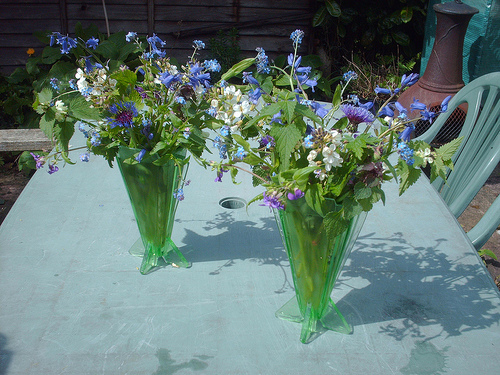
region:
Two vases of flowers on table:
[32, 18, 437, 344]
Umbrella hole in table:
[210, 194, 250, 214]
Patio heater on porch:
[392, 1, 478, 150]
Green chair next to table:
[411, 69, 498, 247]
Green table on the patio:
[2, 84, 493, 373]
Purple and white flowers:
[30, 15, 457, 205]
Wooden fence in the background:
[2, 0, 325, 102]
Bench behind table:
[0, 127, 62, 155]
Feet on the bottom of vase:
[272, 286, 357, 343]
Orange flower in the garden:
[15, 43, 42, 69]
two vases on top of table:
[11, 30, 462, 343]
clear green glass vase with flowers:
[98, 139, 194, 272]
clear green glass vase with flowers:
[271, 188, 369, 342]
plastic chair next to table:
[399, 70, 498, 248]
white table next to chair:
[0, 97, 496, 372]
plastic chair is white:
[407, 67, 497, 256]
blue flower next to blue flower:
[202, 57, 223, 73]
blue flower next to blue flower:
[384, 71, 396, 93]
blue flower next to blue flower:
[402, 125, 413, 143]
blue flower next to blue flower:
[104, 99, 143, 130]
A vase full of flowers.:
[208, 29, 460, 349]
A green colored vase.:
[271, 189, 368, 345]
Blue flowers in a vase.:
[18, 17, 255, 277]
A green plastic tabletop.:
[0, 95, 499, 372]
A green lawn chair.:
[406, 68, 499, 248]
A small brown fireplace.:
[392, 1, 479, 141]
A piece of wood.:
[0, 124, 67, 152]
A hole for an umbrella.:
[220, 195, 247, 212]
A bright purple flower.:
[258, 191, 288, 211]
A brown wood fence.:
[1, 0, 313, 85]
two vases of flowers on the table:
[59, 34, 393, 340]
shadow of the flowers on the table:
[362, 230, 491, 345]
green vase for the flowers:
[284, 206, 348, 343]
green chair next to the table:
[421, 74, 486, 222]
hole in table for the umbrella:
[216, 192, 248, 217]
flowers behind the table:
[8, 37, 33, 117]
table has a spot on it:
[148, 336, 208, 373]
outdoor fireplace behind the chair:
[401, 8, 468, 133]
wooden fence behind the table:
[148, 8, 264, 54]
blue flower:
[396, 72, 416, 91]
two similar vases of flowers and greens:
[2, 5, 493, 370]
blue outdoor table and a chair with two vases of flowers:
[12, 3, 495, 368]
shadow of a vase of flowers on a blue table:
[328, 232, 493, 337]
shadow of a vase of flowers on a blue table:
[163, 208, 295, 295]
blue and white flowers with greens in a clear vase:
[22, 29, 244, 272]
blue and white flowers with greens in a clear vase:
[195, 30, 457, 345]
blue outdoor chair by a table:
[407, 69, 497, 248]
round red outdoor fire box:
[397, 1, 477, 158]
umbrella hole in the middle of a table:
[217, 195, 248, 211]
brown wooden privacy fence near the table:
[5, 2, 335, 124]